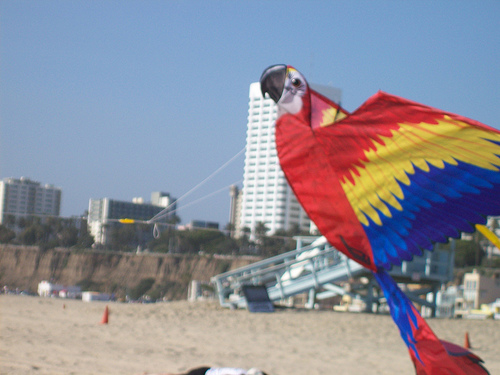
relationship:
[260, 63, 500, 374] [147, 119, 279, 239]
kite has strings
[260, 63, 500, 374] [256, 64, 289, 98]
kite has a beak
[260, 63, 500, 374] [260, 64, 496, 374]
kite looks like a parrot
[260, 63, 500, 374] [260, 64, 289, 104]
kite has a beak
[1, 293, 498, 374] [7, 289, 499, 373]
sand has no people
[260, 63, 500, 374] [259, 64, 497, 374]
kite shaped like parrot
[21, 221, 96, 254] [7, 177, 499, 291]
trees are in background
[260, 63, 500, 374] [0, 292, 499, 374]
kite at beach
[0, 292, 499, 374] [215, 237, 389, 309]
beach has a walkway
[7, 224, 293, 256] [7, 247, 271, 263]
shrubbery along fence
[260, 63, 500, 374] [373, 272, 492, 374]
kite has a tail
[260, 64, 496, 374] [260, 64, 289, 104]
parrot has a beak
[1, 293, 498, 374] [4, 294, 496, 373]
sand has dirt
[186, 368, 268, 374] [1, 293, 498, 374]
person on sand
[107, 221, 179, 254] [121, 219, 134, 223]
building has yellow object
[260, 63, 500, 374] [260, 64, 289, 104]
kite has beak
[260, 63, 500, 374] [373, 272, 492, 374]
kite has tail